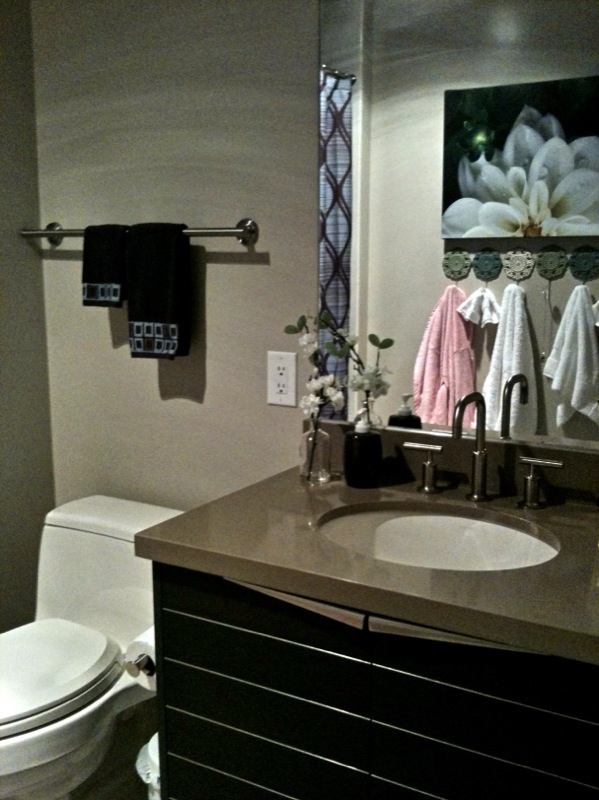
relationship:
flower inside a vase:
[311, 341, 408, 440] [311, 389, 408, 475]